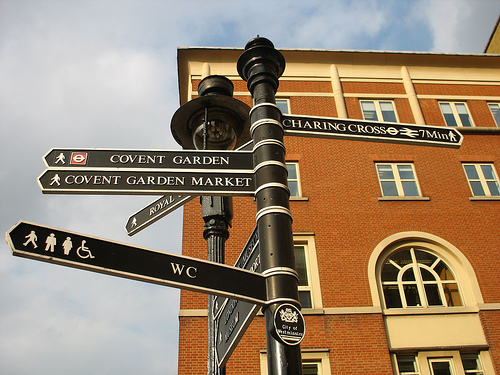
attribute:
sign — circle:
[175, 46, 322, 193]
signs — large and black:
[59, 149, 259, 190]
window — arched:
[370, 229, 486, 311]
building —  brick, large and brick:
[174, 46, 496, 372]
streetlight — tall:
[170, 67, 253, 158]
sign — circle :
[267, 297, 308, 350]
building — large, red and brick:
[133, 30, 498, 343]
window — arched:
[349, 224, 498, 374]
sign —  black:
[44, 215, 267, 307]